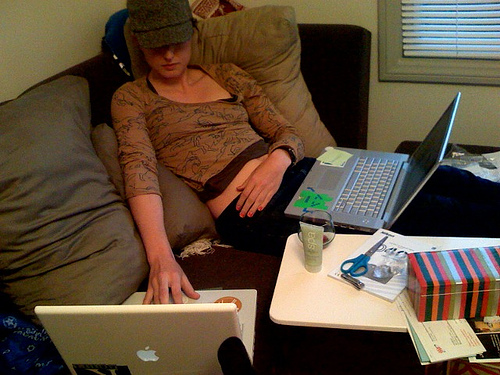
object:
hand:
[235, 163, 292, 219]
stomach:
[202, 182, 235, 215]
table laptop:
[283, 89, 463, 236]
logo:
[134, 346, 160, 362]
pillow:
[120, 2, 335, 161]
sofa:
[2, 4, 370, 374]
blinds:
[399, 0, 499, 60]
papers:
[401, 316, 488, 368]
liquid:
[310, 232, 319, 245]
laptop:
[32, 287, 259, 375]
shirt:
[111, 63, 305, 203]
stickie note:
[316, 147, 352, 170]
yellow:
[314, 146, 350, 168]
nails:
[239, 212, 246, 218]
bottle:
[301, 221, 323, 273]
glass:
[297, 209, 335, 249]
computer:
[32, 286, 259, 375]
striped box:
[404, 247, 500, 323]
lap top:
[281, 91, 465, 235]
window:
[400, 1, 498, 58]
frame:
[377, 1, 499, 86]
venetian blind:
[401, 1, 498, 56]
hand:
[138, 261, 201, 307]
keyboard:
[330, 154, 399, 216]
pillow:
[0, 74, 148, 323]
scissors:
[340, 234, 388, 277]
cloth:
[0, 303, 65, 375]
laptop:
[279, 91, 460, 234]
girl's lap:
[210, 154, 499, 258]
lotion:
[299, 220, 323, 272]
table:
[277, 257, 362, 327]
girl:
[107, 0, 499, 305]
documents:
[407, 315, 488, 366]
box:
[406, 245, 499, 323]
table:
[128, 139, 500, 375]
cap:
[124, 0, 192, 50]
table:
[267, 229, 500, 335]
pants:
[212, 153, 500, 257]